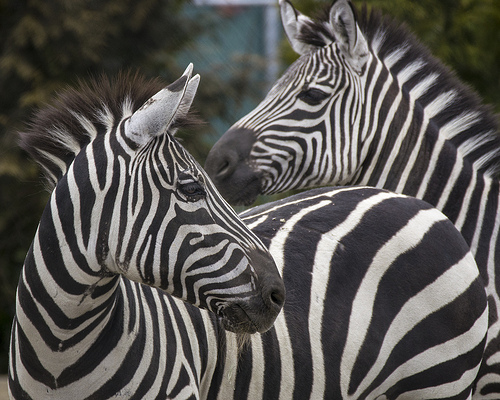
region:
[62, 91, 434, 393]
LARGE BLACK AND WHITE ZEBRA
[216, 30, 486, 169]
LARGE BLACK AND WHITE ZEBRA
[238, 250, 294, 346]
BLACK NOSE ON ZEBRA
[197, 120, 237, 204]
BLACK NOSE ON ZEBRA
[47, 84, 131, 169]
STIFF MANE OF ZEBRA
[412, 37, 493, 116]
STIFF MANE OF ZEBRA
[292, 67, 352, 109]
SMALL DARK EYE OF ZEBRA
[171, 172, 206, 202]
SMALL DARK EYE OF ZEBRA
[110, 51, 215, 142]
POINTED EAR OF ZEBRA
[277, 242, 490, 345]
BLACK AND WHITE STRIPES ON ZEBRA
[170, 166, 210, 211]
eye of a zebra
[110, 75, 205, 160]
ears of a zebra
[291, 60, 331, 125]
eye of a zebra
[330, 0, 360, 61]
ear of a zebra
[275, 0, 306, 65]
ear of a zebra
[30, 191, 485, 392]
zebra standing next to a zebra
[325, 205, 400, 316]
stripes of a zebra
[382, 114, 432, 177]
stripes of a zebra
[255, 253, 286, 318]
nose of a zebra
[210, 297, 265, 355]
mouth of a zebra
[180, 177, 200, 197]
the eye of the zebra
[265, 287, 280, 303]
the inner nostril of the zebra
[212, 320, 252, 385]
the whiskers on the mouth of the zebra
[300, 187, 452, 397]
The hind end of the zebra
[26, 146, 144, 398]
The balck and white stripes on the neck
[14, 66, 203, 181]
the mohawk of the zebra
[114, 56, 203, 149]
the ears of the zebra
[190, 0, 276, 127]
the grren fence between the trees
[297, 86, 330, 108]
the black eye on the zebras face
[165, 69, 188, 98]
a black spot on the zebra ear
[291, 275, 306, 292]
stripe of a zebra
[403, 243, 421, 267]
back of a zebra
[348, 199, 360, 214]
part of a body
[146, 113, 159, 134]
ear of a zebra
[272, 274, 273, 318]
nose of a zebra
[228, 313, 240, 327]
mouth of a zebra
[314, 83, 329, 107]
eye of a zebra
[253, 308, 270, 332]
mouth of a zebra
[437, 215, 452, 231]
back of a zebra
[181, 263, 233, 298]
part of a zebra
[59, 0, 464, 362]
zebras next to each other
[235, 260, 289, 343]
zebra has black nose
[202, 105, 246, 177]
zebra in back has grey nose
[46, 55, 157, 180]
zebra has long black and white mane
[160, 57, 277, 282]
narrow stripes on zebra's face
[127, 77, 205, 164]
zebras have white ears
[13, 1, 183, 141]
green trees behind zebras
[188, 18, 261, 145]
green wall of building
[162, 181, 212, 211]
zebra's eye is black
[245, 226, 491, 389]
zebra has wide stripes on rump